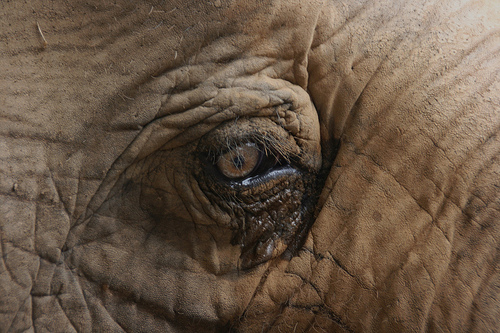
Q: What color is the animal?
A: Brown.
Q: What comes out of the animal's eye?
A: Tears.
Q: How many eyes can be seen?
A: One.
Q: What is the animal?
A: An elephant.